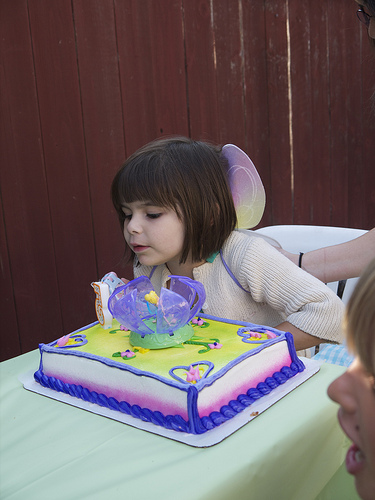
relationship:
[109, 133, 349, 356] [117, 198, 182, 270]
child has face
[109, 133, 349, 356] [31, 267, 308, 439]
child looking at cake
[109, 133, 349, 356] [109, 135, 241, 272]
child has head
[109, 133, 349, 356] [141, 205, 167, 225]
child has eye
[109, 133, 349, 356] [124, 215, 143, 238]
child has nose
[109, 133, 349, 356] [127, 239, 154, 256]
child has mouth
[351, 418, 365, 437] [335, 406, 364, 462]
birthmark over top lip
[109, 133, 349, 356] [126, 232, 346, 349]
child wearing sweater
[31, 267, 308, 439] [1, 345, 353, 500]
cake sitting on table cloth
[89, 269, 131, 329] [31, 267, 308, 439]
candle on top of cake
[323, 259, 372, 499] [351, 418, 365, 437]
boy has birthmark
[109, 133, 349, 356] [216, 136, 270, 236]
child wearing wing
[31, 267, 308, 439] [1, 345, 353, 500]
cake on top of table cloth